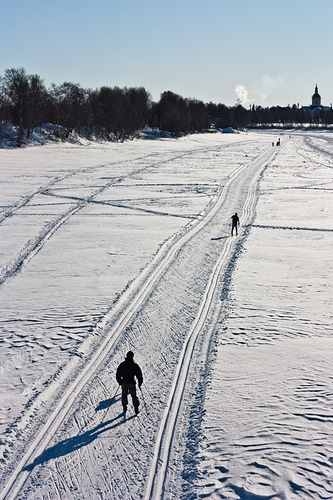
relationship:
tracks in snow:
[17, 162, 281, 479] [34, 185, 298, 378]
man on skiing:
[113, 349, 151, 438] [98, 348, 151, 433]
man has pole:
[113, 349, 151, 438] [137, 380, 147, 407]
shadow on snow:
[8, 420, 126, 469] [34, 185, 298, 378]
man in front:
[215, 203, 247, 242] [185, 166, 285, 214]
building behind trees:
[298, 83, 329, 119] [8, 88, 278, 137]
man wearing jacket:
[113, 349, 151, 438] [103, 365, 152, 386]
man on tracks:
[114, 349, 142, 420] [17, 162, 281, 479]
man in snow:
[113, 349, 151, 438] [34, 185, 298, 378]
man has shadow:
[228, 212, 240, 236] [210, 227, 227, 250]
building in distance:
[300, 83, 332, 125] [187, 91, 327, 142]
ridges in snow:
[43, 158, 314, 244] [34, 185, 298, 378]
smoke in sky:
[213, 77, 274, 115] [8, 10, 331, 105]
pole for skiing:
[100, 380, 168, 428] [78, 384, 178, 461]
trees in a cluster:
[8, 88, 278, 137] [9, 97, 267, 162]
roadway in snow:
[72, 149, 282, 496] [34, 185, 298, 378]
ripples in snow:
[22, 185, 210, 273] [34, 185, 298, 378]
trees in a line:
[8, 88, 278, 137] [17, 136, 271, 148]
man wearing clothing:
[228, 212, 240, 236] [228, 218, 242, 232]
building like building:
[300, 83, 332, 125] [298, 83, 329, 119]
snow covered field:
[34, 185, 298, 378] [6, 153, 333, 480]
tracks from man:
[17, 162, 281, 479] [114, 349, 142, 420]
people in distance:
[273, 137, 280, 149] [187, 91, 327, 142]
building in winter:
[300, 83, 332, 125] [7, 32, 302, 360]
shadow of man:
[8, 420, 126, 469] [114, 349, 142, 420]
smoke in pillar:
[213, 77, 274, 115] [235, 84, 247, 110]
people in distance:
[261, 129, 312, 166] [187, 91, 327, 142]